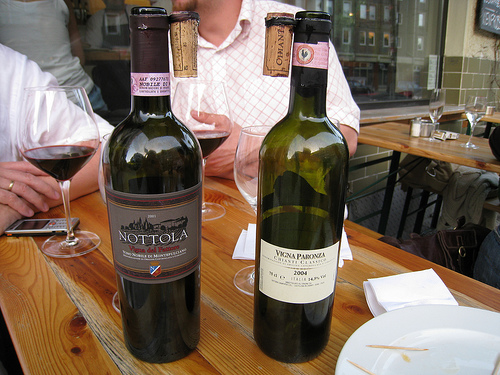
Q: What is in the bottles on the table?
A: Wine.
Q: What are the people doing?
A: Drinking wine and talking.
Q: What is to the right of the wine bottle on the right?
A: A white plate.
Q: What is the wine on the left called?
A: Nottola.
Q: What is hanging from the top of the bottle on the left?
A: A cork.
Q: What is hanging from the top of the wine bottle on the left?
A: A cork.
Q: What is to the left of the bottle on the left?
A: A glass of red wine.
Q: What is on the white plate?
A: Toothpicks.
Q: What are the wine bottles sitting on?
A: A wood table.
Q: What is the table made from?
A: Wood.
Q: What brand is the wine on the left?
A: Nottola.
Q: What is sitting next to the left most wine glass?
A: A phone.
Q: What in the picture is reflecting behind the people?
A: A window.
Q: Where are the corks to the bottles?
A: Attached to the neck of the bottles.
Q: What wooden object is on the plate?
A: Toothpicks.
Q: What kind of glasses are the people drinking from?
A: Wine glasses.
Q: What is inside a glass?
A: Red wine.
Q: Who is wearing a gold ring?
A: A person.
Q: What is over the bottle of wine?
A: A label.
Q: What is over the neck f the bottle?
A: A label.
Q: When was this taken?
A: Daytime.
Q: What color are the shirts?
A: White.